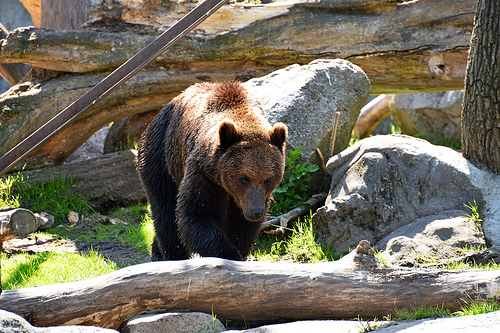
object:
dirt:
[198, 202, 205, 208]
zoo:
[0, 0, 499, 332]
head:
[217, 120, 288, 222]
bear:
[132, 79, 290, 269]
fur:
[203, 74, 247, 114]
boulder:
[237, 54, 373, 186]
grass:
[0, 131, 498, 332]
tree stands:
[456, 0, 500, 176]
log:
[0, 148, 150, 223]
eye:
[235, 176, 251, 188]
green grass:
[0, 159, 98, 226]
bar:
[0, 0, 227, 179]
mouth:
[236, 202, 274, 223]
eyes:
[263, 179, 273, 188]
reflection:
[240, 66, 312, 111]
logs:
[0, 0, 478, 175]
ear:
[213, 119, 245, 151]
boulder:
[308, 132, 500, 270]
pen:
[0, 0, 499, 331]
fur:
[148, 104, 208, 158]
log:
[0, 238, 499, 330]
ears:
[266, 121, 289, 146]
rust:
[0, 0, 223, 173]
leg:
[173, 148, 242, 262]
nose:
[251, 206, 267, 218]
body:
[131, 79, 288, 261]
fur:
[178, 185, 215, 252]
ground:
[0, 132, 499, 331]